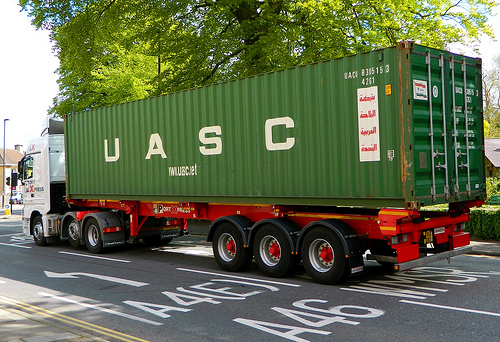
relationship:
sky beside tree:
[8, 8, 113, 113] [63, 10, 275, 55]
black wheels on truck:
[48, 210, 405, 286] [20, 40, 486, 283]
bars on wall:
[426, 49, 471, 201] [411, 47, 484, 203]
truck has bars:
[20, 40, 486, 283] [426, 49, 471, 201]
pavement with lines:
[145, 270, 279, 327] [6, 237, 486, 322]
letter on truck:
[97, 133, 127, 165] [20, 40, 486, 283]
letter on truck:
[144, 132, 167, 160] [20, 40, 486, 283]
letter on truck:
[188, 120, 227, 160] [20, 40, 486, 283]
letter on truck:
[264, 116, 295, 152] [20, 40, 486, 283]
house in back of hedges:
[482, 135, 499, 172] [487, 175, 499, 200]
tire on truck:
[296, 220, 363, 282] [377, 85, 444, 157]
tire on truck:
[251, 222, 300, 276] [377, 85, 444, 157]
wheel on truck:
[211, 222, 243, 273] [377, 85, 444, 157]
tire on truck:
[296, 220, 363, 282] [20, 40, 486, 283]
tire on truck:
[251, 222, 300, 276] [20, 40, 486, 283]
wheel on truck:
[211, 222, 243, 273] [20, 40, 486, 283]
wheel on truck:
[83, 216, 105, 251] [20, 40, 486, 283]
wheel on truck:
[65, 217, 82, 246] [20, 40, 486, 283]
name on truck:
[93, 110, 304, 181] [9, 22, 489, 290]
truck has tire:
[20, 40, 486, 283] [296, 220, 363, 282]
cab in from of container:
[19, 116, 64, 236] [64, 40, 486, 208]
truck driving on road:
[20, 40, 486, 283] [0, 224, 499, 341]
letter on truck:
[197, 125, 224, 157] [20, 40, 486, 283]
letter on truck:
[260, 112, 295, 152] [20, 40, 486, 283]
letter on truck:
[103, 137, 121, 163] [20, 40, 486, 283]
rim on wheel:
[67, 221, 80, 242] [58, 208, 85, 246]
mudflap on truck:
[343, 239, 374, 284] [20, 40, 486, 283]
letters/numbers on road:
[121, 274, 383, 339] [0, 224, 499, 341]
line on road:
[177, 266, 299, 286] [0, 224, 499, 341]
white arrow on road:
[43, 267, 149, 289] [0, 224, 499, 341]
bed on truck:
[63, 197, 483, 265] [20, 40, 486, 283]